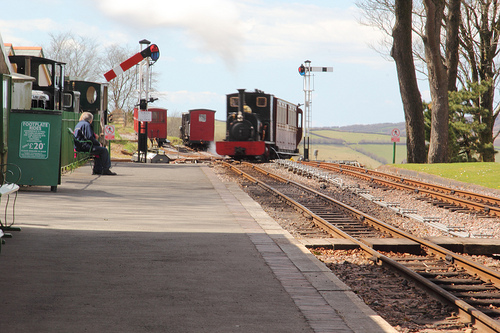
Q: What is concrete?
A: The pavement.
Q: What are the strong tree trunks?
A: Tall.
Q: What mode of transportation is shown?
A: Train.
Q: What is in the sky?
A: Clouds.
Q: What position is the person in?
A: Sitting.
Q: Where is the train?
A: Tracks.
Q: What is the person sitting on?
A: Chair.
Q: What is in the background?
A: Fields.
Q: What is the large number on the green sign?
A: 20.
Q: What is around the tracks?
A: Gravel.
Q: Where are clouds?
A: In the sky.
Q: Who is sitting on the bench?
A: An old man.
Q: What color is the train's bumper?
A: Red.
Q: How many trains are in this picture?
A: 1.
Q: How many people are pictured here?
A: 1.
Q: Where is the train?
A: On the tracks.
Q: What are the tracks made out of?
A: Metal.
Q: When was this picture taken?
A: Daytime.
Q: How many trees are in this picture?
A: 8.